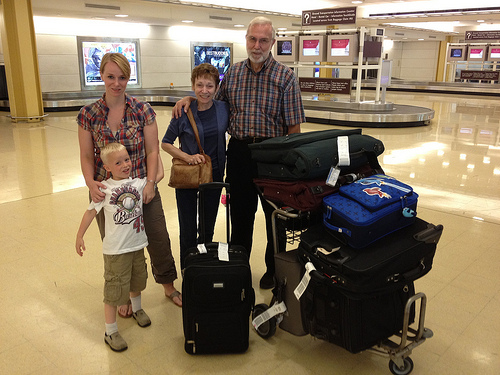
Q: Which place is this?
A: It is an airport.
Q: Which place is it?
A: It is an airport.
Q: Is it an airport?
A: Yes, it is an airport.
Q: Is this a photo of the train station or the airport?
A: It is showing the airport.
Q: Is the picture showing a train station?
A: No, the picture is showing an airport.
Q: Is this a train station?
A: No, it is an airport.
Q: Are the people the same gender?
A: Yes, all the people are female.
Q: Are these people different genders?
A: No, all the people are female.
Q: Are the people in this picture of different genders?
A: No, all the people are female.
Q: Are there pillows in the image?
A: No, there are no pillows.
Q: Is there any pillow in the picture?
A: No, there are no pillows.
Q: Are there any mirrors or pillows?
A: No, there are no pillows or mirrors.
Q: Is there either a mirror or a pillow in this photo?
A: No, there are no pillows or mirrors.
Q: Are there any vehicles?
A: No, there are no vehicles.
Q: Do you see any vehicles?
A: No, there are no vehicles.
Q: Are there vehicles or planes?
A: No, there are no vehicles or planes.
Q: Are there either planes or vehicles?
A: No, there are no vehicles or planes.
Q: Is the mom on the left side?
A: Yes, the mom is on the left of the image.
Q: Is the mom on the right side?
A: No, the mom is on the left of the image.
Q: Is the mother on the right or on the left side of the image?
A: The mother is on the left of the image.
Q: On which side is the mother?
A: The mother is on the left of the image.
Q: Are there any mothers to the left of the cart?
A: Yes, there is a mother to the left of the cart.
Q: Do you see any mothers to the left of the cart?
A: Yes, there is a mother to the left of the cart.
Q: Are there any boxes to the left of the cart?
A: No, there is a mother to the left of the cart.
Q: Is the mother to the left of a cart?
A: Yes, the mother is to the left of a cart.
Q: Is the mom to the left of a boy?
A: No, the mom is to the left of a cart.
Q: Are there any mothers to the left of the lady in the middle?
A: Yes, there is a mother to the left of the lady.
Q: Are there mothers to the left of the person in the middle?
A: Yes, there is a mother to the left of the lady.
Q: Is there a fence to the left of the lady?
A: No, there is a mother to the left of the lady.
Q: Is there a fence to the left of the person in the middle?
A: No, there is a mother to the left of the lady.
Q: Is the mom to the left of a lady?
A: Yes, the mom is to the left of a lady.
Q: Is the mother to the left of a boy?
A: No, the mother is to the left of a lady.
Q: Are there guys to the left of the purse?
A: No, there is a mother to the left of the purse.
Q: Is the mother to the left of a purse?
A: Yes, the mother is to the left of a purse.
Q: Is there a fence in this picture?
A: No, there are no fences.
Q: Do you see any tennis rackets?
A: No, there are no tennis rackets.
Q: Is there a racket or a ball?
A: No, there are no rackets or balls.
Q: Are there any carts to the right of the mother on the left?
A: Yes, there is a cart to the right of the mother.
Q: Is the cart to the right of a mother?
A: Yes, the cart is to the right of a mother.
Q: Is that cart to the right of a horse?
A: No, the cart is to the right of a mother.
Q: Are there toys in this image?
A: No, there are no toys.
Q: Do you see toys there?
A: No, there are no toys.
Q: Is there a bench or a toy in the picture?
A: No, there are no toys or benches.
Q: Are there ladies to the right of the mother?
A: Yes, there is a lady to the right of the mother.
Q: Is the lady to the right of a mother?
A: Yes, the lady is to the right of a mother.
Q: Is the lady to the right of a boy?
A: No, the lady is to the right of a mother.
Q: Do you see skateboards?
A: No, there are no skateboards.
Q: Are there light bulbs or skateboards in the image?
A: No, there are no skateboards or light bulbs.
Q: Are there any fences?
A: No, there are no fences.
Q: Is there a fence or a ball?
A: No, there are no fences or balls.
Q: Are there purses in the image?
A: Yes, there is a purse.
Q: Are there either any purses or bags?
A: Yes, there is a purse.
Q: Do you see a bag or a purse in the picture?
A: Yes, there is a purse.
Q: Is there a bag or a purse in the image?
A: Yes, there is a purse.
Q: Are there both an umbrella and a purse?
A: No, there is a purse but no umbrellas.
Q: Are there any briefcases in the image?
A: No, there are no briefcases.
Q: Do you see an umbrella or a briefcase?
A: No, there are no briefcases or umbrellas.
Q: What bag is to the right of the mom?
A: The bag is a purse.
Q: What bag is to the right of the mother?
A: The bag is a purse.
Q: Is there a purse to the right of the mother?
A: Yes, there is a purse to the right of the mother.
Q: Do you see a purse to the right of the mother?
A: Yes, there is a purse to the right of the mother.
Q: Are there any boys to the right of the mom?
A: No, there is a purse to the right of the mom.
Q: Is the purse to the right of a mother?
A: Yes, the purse is to the right of a mother.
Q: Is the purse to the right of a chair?
A: No, the purse is to the right of a mother.